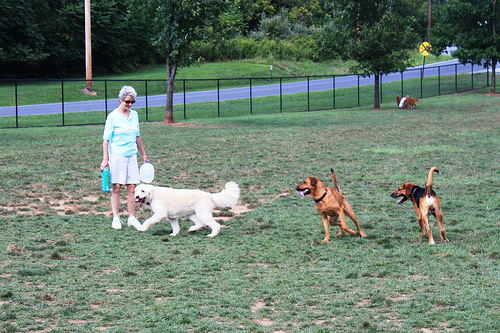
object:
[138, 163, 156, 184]
bottle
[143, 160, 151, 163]
top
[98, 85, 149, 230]
woman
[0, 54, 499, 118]
road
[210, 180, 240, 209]
tail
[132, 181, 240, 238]
dog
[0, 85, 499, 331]
grass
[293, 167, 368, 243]
dog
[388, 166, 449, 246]
dog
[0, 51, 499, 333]
field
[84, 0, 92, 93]
pole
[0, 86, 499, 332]
scene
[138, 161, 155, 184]
water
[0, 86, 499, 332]
dog park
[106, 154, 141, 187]
shorts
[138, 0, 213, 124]
small tree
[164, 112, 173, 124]
mud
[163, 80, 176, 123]
trunk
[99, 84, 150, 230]
lady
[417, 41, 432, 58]
sign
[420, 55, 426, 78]
pole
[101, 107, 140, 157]
shirt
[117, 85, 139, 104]
hair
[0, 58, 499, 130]
fence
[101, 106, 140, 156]
clothing